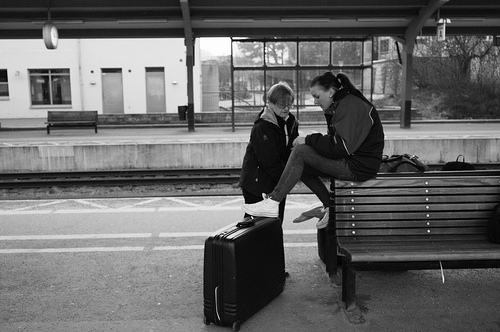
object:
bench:
[42, 107, 100, 137]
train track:
[2, 161, 248, 192]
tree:
[387, 35, 496, 118]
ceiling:
[1, 1, 498, 53]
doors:
[143, 64, 167, 114]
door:
[98, 59, 127, 117]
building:
[2, 39, 243, 117]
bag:
[380, 150, 428, 177]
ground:
[1, 118, 500, 332]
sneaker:
[313, 205, 333, 231]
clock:
[40, 21, 60, 51]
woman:
[239, 82, 300, 276]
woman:
[240, 53, 386, 222]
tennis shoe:
[241, 191, 287, 220]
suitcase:
[203, 214, 287, 331]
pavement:
[0, 118, 499, 330]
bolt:
[342, 159, 437, 237]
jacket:
[303, 86, 389, 179]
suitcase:
[198, 208, 291, 331]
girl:
[241, 68, 383, 228]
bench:
[318, 170, 499, 302]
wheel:
[228, 321, 237, 329]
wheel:
[199, 317, 209, 327]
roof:
[2, 3, 499, 33]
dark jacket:
[238, 104, 301, 199]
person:
[237, 76, 301, 288]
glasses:
[272, 99, 295, 112]